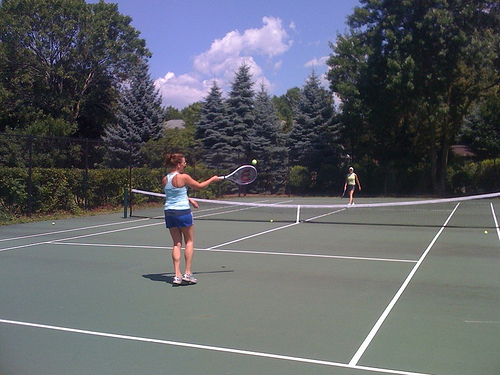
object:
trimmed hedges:
[451, 155, 499, 192]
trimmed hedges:
[0, 169, 230, 213]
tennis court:
[1, 197, 498, 372]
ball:
[251, 159, 257, 165]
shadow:
[141, 270, 239, 287]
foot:
[172, 274, 182, 284]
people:
[160, 154, 362, 285]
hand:
[211, 176, 219, 182]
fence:
[126, 181, 498, 226]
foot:
[181, 271, 197, 283]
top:
[160, 169, 190, 211]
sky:
[125, 1, 372, 112]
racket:
[218, 165, 259, 186]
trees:
[106, 73, 163, 167]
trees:
[208, 75, 299, 187]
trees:
[276, 80, 356, 177]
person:
[159, 153, 221, 287]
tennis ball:
[270, 219, 274, 223]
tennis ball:
[51, 221, 55, 225]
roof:
[164, 119, 187, 129]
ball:
[484, 230, 489, 234]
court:
[0, 195, 500, 374]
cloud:
[154, 12, 339, 117]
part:
[219, 43, 235, 58]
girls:
[160, 153, 217, 284]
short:
[164, 209, 194, 228]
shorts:
[346, 185, 355, 191]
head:
[162, 153, 187, 173]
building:
[449, 145, 486, 162]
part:
[304, 50, 328, 71]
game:
[3, 148, 500, 375]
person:
[342, 167, 362, 206]